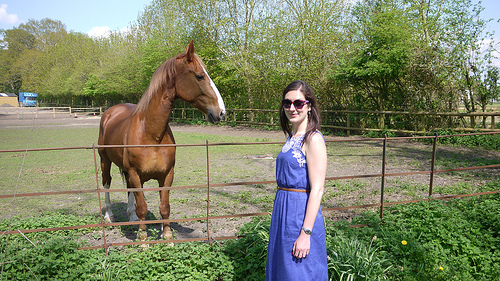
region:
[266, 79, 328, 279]
Woman in purple sleeveless dress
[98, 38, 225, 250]
Brown and white horse standing near fence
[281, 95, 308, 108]
Sunglasses on woman's face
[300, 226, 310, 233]
Watch on woman's wrist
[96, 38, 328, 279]
Woman standing close to horse behind fence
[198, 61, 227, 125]
White patch on horse's face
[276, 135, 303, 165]
White pattern on purple dress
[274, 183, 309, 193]
Brown belt around woman's waist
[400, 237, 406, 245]
Yellow flower in the bushes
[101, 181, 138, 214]
White patches on horse's back legs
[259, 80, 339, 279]
A woman in a purple dress.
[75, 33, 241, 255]
a horse near a fence.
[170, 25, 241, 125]
a horse with a brown head.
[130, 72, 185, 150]
a neck on a horse.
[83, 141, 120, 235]
a right hind leg.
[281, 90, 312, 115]
a woman with a pair of sunglasses.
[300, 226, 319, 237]
a watch on a woman's wrist.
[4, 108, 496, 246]
a large field with grass.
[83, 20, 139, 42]
a large white cloud.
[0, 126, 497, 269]
a metal fence.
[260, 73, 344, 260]
the woman beside the horse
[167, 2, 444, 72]
the trees with green leaves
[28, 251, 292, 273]
the bushes beside the fence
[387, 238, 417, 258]
the yellow flower in the bushes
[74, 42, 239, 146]
the horse in the pen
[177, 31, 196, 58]
the ear of the horse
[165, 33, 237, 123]
the head of the horse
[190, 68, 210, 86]
the eye of the horse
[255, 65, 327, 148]
the woman wearing sunglasses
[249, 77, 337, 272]
the woman wearing blue dress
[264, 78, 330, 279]
woman in a blue dress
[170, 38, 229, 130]
brown horse with a white nose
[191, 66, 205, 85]
eye on a horse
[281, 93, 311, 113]
sunglasses on a woman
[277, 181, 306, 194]
brown belt on a woman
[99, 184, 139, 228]
white hind legs of a horse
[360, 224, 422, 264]
yellow flowers on a bush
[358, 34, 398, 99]
green leaves on a tree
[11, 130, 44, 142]
short green grass in a field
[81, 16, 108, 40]
clouds peaking over the tree tops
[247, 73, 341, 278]
the woman beside the fence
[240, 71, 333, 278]
the woman wearing sunglasses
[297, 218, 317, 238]
the watch on the wrist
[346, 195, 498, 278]
the green bushes beside the fence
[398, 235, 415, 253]
the yellow flower in the grass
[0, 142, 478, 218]
the fence is rusted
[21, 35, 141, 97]
the trees with green leaves